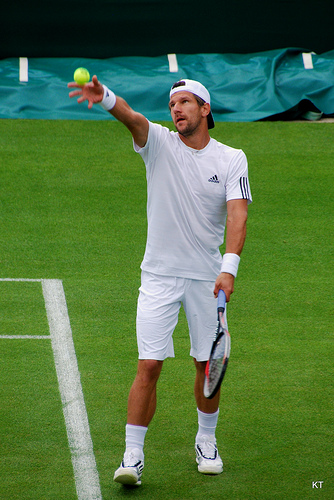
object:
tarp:
[0, 46, 334, 125]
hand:
[67, 75, 103, 108]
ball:
[74, 67, 90, 84]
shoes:
[114, 452, 144, 485]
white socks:
[125, 425, 147, 450]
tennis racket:
[203, 291, 231, 399]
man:
[69, 73, 251, 484]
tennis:
[74, 67, 90, 83]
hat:
[170, 78, 215, 129]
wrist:
[221, 253, 240, 278]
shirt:
[131, 121, 252, 282]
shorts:
[136, 271, 230, 361]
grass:
[0, 120, 334, 499]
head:
[169, 79, 210, 134]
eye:
[170, 105, 174, 108]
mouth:
[177, 118, 186, 123]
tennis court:
[0, 114, 334, 500]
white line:
[43, 277, 103, 499]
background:
[0, 0, 333, 124]